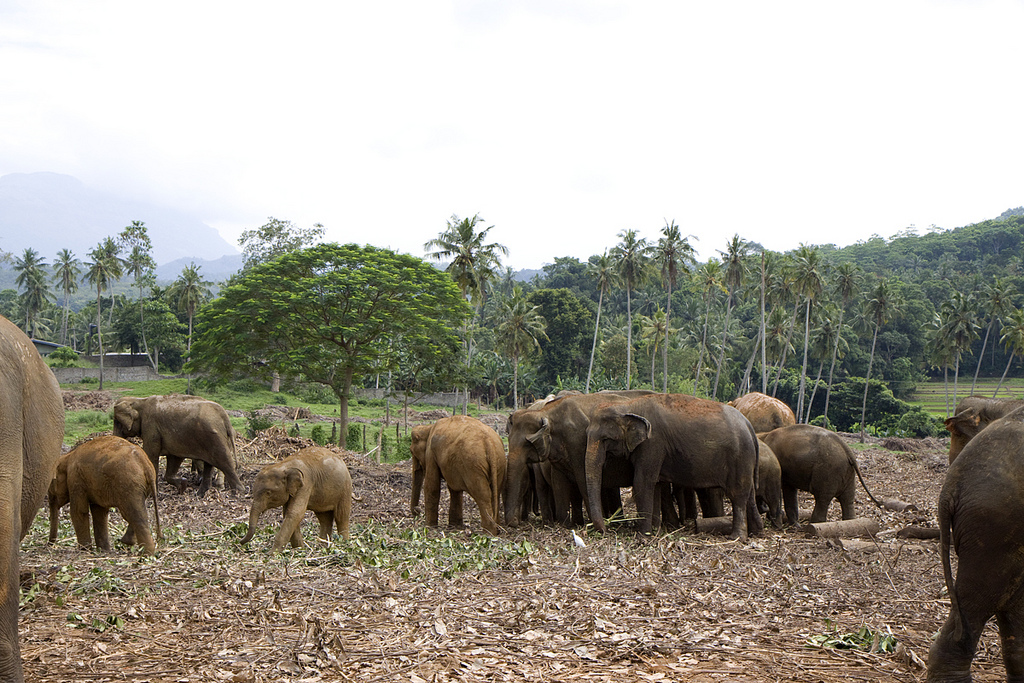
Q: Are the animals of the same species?
A: Yes, all the animals are elephants.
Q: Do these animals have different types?
A: No, all the animals are elephants.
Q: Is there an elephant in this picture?
A: Yes, there is an elephant.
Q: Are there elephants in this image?
A: Yes, there is an elephant.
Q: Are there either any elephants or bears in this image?
A: Yes, there is an elephant.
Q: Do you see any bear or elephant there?
A: Yes, there is an elephant.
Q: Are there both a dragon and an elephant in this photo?
A: No, there is an elephant but no dragons.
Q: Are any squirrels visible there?
A: No, there are no squirrels.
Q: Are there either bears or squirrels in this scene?
A: No, there are no squirrels or bears.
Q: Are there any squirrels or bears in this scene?
A: No, there are no squirrels or bears.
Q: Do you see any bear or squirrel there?
A: No, there are no squirrels or bears.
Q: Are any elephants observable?
A: Yes, there is an elephant.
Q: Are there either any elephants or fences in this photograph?
A: Yes, there is an elephant.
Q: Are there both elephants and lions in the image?
A: No, there is an elephant but no lions.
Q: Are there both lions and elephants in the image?
A: No, there is an elephant but no lions.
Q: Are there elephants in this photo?
A: Yes, there is an elephant.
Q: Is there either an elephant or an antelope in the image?
A: Yes, there is an elephant.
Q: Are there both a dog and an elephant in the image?
A: No, there is an elephant but no dogs.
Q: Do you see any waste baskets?
A: No, there are no waste baskets.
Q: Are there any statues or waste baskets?
A: No, there are no waste baskets or statues.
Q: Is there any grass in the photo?
A: Yes, there is grass.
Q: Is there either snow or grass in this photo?
A: Yes, there is grass.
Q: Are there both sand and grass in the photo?
A: No, there is grass but no sand.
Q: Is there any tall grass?
A: Yes, there is tall grass.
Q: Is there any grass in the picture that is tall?
A: Yes, there is grass that is tall.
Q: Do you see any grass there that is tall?
A: Yes, there is grass that is tall.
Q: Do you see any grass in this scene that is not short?
A: Yes, there is tall grass.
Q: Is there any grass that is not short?
A: Yes, there is tall grass.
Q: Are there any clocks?
A: No, there are no clocks.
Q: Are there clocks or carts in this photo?
A: No, there are no clocks or carts.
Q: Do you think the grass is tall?
A: Yes, the grass is tall.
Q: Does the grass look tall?
A: Yes, the grass is tall.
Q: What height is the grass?
A: The grass is tall.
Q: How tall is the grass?
A: The grass is tall.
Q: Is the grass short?
A: No, the grass is tall.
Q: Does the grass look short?
A: No, the grass is tall.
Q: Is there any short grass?
A: No, there is grass but it is tall.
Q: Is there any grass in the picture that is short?
A: No, there is grass but it is tall.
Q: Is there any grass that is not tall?
A: No, there is grass but it is tall.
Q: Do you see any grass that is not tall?
A: No, there is grass but it is tall.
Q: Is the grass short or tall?
A: The grass is tall.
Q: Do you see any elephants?
A: Yes, there is an elephant.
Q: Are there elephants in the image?
A: Yes, there is an elephant.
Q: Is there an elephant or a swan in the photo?
A: Yes, there is an elephant.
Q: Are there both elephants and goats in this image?
A: No, there is an elephant but no goats.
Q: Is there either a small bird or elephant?
A: Yes, there is a small elephant.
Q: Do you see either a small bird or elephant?
A: Yes, there is a small elephant.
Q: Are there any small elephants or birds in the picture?
A: Yes, there is a small elephant.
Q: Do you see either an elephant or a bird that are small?
A: Yes, the elephant is small.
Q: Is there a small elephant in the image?
A: Yes, there is a small elephant.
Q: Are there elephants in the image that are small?
A: Yes, there is an elephant that is small.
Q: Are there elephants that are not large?
A: Yes, there is a small elephant.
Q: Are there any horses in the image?
A: No, there are no horses.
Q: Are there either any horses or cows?
A: No, there are no horses or cows.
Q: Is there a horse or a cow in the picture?
A: No, there are no horses or cows.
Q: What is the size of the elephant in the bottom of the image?
A: The elephant is small.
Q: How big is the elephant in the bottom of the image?
A: The elephant is small.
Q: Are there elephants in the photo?
A: Yes, there is an elephant.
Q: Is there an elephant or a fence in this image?
A: Yes, there is an elephant.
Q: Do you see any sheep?
A: No, there are no sheep.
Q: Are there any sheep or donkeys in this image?
A: No, there are no sheep or donkeys.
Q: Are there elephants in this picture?
A: Yes, there is an elephant.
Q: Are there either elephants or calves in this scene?
A: Yes, there is an elephant.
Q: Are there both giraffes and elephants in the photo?
A: No, there is an elephant but no giraffes.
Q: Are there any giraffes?
A: No, there are no giraffes.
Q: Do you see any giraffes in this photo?
A: No, there are no giraffes.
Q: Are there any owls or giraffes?
A: No, there are no giraffes or owls.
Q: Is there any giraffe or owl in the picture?
A: No, there are no giraffes or owls.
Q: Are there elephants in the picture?
A: Yes, there is an elephant.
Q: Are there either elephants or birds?
A: Yes, there is an elephant.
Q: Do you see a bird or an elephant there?
A: Yes, there is an elephant.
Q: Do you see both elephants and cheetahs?
A: No, there is an elephant but no cheetahs.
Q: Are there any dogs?
A: No, there are no dogs.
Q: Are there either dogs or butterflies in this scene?
A: No, there are no dogs or butterflies.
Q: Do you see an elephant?
A: Yes, there is an elephant.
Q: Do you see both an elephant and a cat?
A: No, there is an elephant but no cats.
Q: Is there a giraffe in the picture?
A: No, there are no giraffes.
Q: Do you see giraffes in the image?
A: No, there are no giraffes.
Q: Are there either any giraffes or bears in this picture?
A: No, there are no giraffes or bears.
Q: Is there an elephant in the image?
A: Yes, there is an elephant.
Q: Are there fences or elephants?
A: Yes, there is an elephant.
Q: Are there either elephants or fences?
A: Yes, there is an elephant.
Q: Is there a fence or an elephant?
A: Yes, there is an elephant.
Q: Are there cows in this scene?
A: No, there are no cows.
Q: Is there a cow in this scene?
A: No, there are no cows.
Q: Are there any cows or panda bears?
A: No, there are no cows or panda bears.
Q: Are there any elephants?
A: Yes, there is an elephant.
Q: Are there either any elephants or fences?
A: Yes, there is an elephant.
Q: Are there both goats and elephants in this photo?
A: No, there is an elephant but no goats.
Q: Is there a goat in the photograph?
A: No, there are no goats.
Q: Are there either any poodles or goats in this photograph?
A: No, there are no goats or poodles.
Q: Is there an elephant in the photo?
A: Yes, there is an elephant.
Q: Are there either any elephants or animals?
A: Yes, there is an elephant.